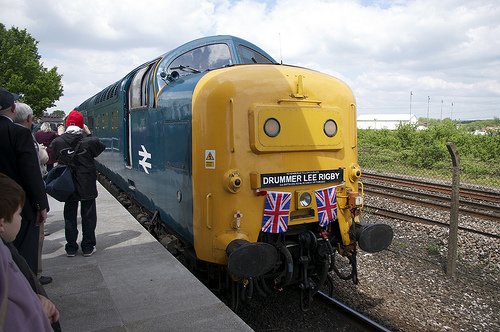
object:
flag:
[261, 191, 291, 233]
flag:
[315, 187, 338, 227]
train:
[62, 33, 391, 279]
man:
[48, 111, 106, 258]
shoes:
[66, 245, 78, 256]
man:
[10, 102, 53, 285]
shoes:
[38, 276, 52, 285]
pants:
[64, 199, 96, 254]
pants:
[37, 219, 44, 279]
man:
[1, 92, 50, 277]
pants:
[13, 222, 39, 278]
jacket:
[47, 132, 106, 201]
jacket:
[0, 116, 50, 220]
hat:
[66, 111, 84, 128]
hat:
[0, 91, 20, 110]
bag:
[43, 165, 75, 202]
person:
[35, 122, 61, 173]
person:
[0, 176, 60, 332]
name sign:
[260, 169, 343, 188]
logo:
[138, 145, 151, 174]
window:
[167, 41, 231, 76]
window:
[239, 44, 274, 64]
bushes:
[399, 137, 447, 167]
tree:
[0, 23, 63, 116]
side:
[1, 2, 252, 332]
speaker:
[225, 238, 278, 278]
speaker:
[348, 222, 394, 253]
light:
[263, 117, 281, 137]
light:
[324, 119, 338, 137]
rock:
[436, 298, 442, 302]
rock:
[480, 251, 484, 256]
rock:
[444, 325, 451, 330]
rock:
[434, 210, 437, 215]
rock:
[385, 202, 387, 205]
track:
[363, 204, 499, 241]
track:
[264, 285, 394, 332]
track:
[358, 189, 497, 221]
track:
[358, 180, 499, 212]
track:
[360, 171, 499, 204]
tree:
[50, 109, 66, 117]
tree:
[493, 117, 499, 126]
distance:
[356, 90, 499, 130]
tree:
[419, 117, 425, 123]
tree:
[443, 116, 451, 124]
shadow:
[41, 240, 255, 331]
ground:
[40, 178, 253, 330]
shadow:
[95, 229, 142, 249]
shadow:
[40, 237, 66, 255]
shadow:
[42, 216, 79, 236]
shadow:
[47, 214, 55, 219]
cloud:
[356, 14, 412, 49]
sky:
[1, 0, 499, 120]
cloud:
[1, 1, 78, 35]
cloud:
[407, 28, 498, 70]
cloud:
[351, 73, 497, 93]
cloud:
[57, 80, 104, 92]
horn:
[160, 71, 179, 81]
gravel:
[389, 278, 498, 330]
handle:
[278, 99, 324, 105]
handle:
[230, 98, 235, 153]